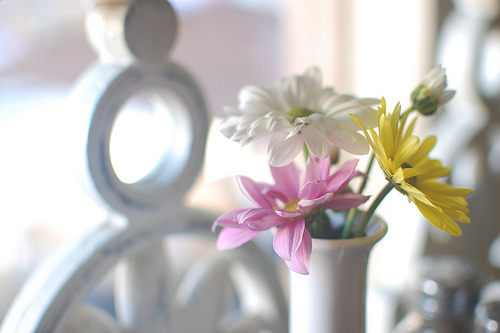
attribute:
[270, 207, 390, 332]
vase — white, whtie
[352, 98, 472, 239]
flower — yellow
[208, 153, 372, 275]
daisy — pink, purple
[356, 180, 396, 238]
stem — green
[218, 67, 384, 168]
bud — white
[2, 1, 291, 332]
decoration — circular, white